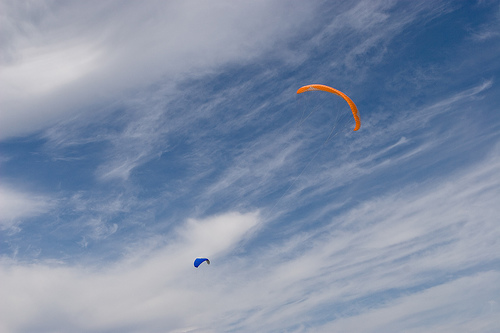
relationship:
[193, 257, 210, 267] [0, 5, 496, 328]
sail in sky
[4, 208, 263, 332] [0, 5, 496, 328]
cloud in sky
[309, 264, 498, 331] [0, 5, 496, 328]
cloud in sky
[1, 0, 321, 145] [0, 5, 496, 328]
cloud in sky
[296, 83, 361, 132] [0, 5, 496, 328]
kite flying in sky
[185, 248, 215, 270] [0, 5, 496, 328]
kite flying in sky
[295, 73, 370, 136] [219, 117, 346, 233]
kite in sky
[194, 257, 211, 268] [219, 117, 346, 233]
kite in sky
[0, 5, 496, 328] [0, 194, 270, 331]
sky between cloud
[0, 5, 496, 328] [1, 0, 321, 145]
sky between cloud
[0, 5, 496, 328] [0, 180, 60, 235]
sky between cloud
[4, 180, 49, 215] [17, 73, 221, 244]
cloud in sky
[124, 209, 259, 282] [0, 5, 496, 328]
cloud in sky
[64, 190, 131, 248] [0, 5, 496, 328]
cloud in sky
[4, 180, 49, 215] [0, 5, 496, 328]
cloud in sky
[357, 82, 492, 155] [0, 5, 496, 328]
cloud in sky